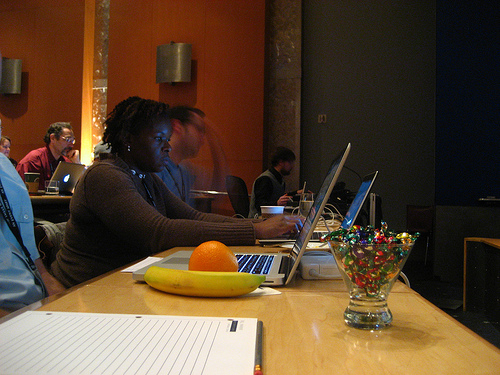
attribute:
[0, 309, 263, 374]
paper — white, for writing, blank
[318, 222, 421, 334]
glass — made of glass, tall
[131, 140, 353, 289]
laptop — computer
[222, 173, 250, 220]
chair — dark brown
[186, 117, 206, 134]
glasses — dark rimmed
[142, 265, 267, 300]
banana — long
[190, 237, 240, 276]
orange — big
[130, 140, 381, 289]
computers — open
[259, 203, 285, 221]
coffee cup — to go, brown, plastic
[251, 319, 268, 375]
pencil — grey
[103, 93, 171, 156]
hair — curly, natural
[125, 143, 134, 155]
earring — small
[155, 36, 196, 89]
scone — silver, gray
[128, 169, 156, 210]
lanyard — dark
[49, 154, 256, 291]
shirt — brown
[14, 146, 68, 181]
shirt — red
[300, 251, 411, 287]
charger — white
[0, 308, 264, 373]
pad — notebook, paper